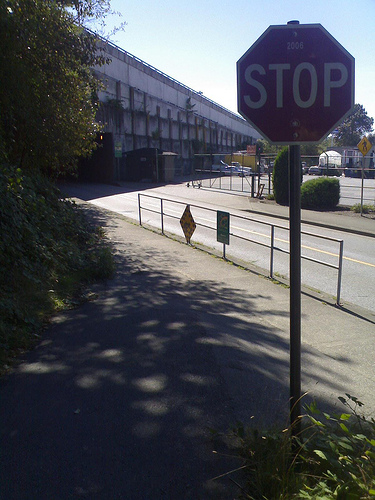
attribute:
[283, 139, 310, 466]
pole — black, metal, straight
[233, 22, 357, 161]
sign — red, white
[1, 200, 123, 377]
grass — green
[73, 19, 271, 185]
bridge — white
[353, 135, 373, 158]
sign — yellow, black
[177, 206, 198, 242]
street sign — triangular, yellow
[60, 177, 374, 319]
road — sectioned, clear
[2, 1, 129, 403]
trees — bushy, some, green, growing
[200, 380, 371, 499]
plant — growing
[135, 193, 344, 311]
fence — metal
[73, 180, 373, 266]
line — yellow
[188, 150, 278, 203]
gate — meshed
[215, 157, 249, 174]
cars — lot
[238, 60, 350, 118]
stop — written bold